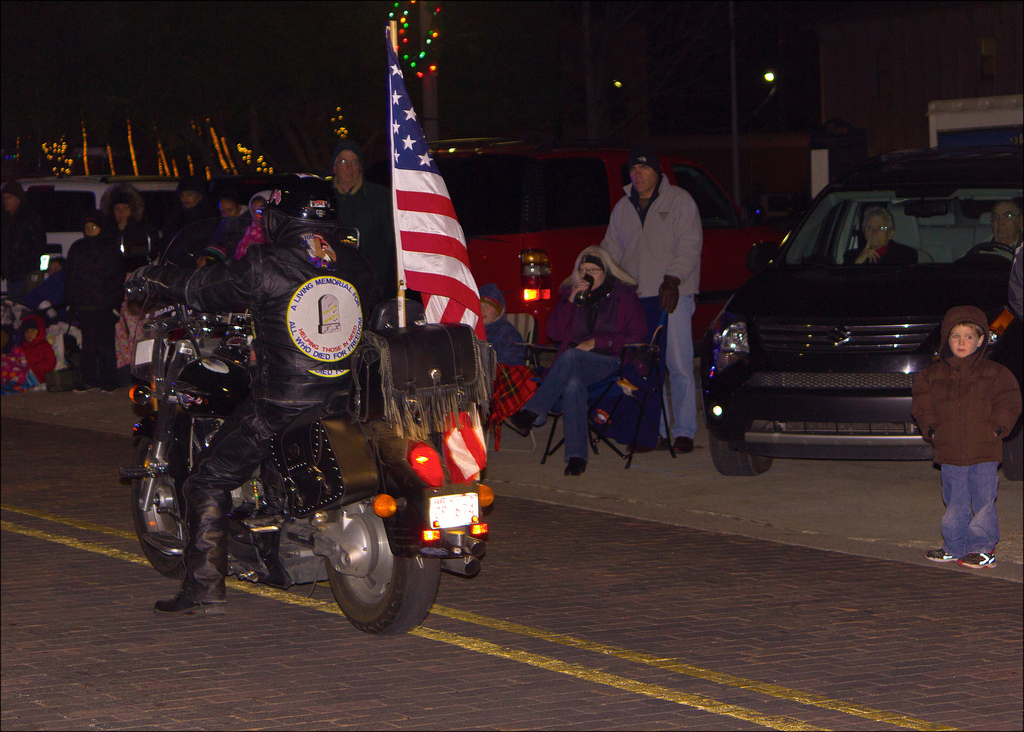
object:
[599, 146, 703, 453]
person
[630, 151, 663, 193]
head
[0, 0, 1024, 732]
outdoors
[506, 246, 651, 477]
person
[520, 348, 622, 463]
jeans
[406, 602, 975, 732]
lines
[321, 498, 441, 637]
tire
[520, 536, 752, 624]
street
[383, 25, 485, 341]
flag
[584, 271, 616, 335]
purple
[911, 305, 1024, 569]
boy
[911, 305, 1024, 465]
jacket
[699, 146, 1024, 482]
car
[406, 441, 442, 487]
light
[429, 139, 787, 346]
suv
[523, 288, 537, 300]
headlight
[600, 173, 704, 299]
sweater